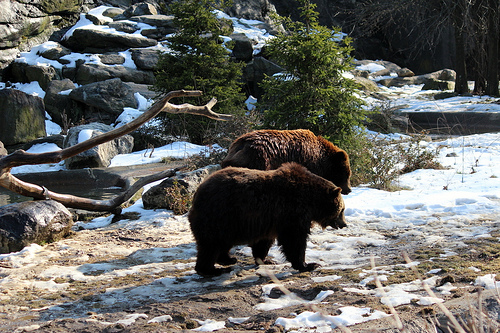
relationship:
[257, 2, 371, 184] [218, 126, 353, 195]
tree behind bear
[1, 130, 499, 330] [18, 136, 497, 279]
ground covered with snow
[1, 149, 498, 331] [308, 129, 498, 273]
ground with snow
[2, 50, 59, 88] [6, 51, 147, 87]
rock with snow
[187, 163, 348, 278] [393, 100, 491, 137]
bear in water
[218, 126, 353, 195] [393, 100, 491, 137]
bear in water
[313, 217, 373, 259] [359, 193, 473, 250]
ripples in river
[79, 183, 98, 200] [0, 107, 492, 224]
ripples in river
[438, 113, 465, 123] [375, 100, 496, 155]
ripples in river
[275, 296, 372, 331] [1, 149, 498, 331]
snow on ground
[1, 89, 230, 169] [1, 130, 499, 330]
tree fallen on ground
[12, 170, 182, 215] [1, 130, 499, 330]
tree fallen on ground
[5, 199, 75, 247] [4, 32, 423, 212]
large rock by fallen tree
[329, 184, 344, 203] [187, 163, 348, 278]
ear of bear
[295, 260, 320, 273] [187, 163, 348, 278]
paw of bear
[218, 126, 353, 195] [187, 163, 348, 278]
bear behind bear